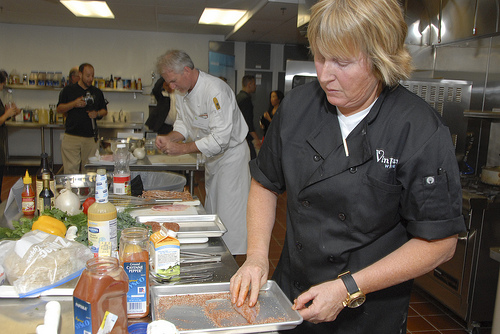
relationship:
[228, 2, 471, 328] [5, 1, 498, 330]
person in kitchen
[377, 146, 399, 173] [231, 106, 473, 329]
logo on top of shirt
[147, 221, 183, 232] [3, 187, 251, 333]
food on top of table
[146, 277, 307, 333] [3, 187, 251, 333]
tray on top of table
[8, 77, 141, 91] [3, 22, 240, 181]
shelf inside background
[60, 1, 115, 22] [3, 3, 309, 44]
light on top of ceiling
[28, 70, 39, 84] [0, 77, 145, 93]
item on top of shelf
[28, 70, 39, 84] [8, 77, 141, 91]
item on top of shelf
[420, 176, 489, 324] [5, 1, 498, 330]
oven inside kitchen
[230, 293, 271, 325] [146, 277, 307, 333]
meat on top of tray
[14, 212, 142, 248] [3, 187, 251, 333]
greens on top of table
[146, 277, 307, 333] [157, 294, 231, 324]
tray has spices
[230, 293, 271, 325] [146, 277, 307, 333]
chicken inside tray